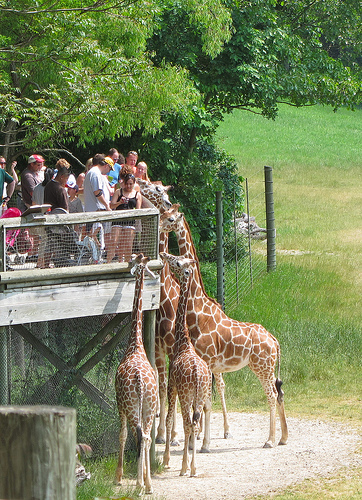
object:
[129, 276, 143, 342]
neck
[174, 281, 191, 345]
neck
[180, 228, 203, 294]
neck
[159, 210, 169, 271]
neck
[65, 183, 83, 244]
people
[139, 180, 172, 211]
head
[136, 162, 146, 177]
head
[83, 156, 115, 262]
man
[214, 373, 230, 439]
leg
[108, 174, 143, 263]
people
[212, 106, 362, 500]
ground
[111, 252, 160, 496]
animal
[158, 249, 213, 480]
animal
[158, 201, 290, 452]
animal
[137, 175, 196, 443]
animal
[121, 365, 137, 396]
brown spots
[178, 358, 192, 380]
brown spots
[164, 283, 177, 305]
brown spots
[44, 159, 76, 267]
people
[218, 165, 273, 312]
fence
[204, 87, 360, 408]
grass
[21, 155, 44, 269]
man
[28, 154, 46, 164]
hat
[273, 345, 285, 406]
tail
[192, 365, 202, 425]
tail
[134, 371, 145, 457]
tail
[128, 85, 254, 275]
trees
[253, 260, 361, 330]
weeds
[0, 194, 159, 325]
high platform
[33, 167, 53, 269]
girl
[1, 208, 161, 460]
fence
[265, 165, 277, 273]
fence poles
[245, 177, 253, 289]
fence poles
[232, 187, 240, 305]
fence poles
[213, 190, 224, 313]
fence poles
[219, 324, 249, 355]
spots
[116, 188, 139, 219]
top